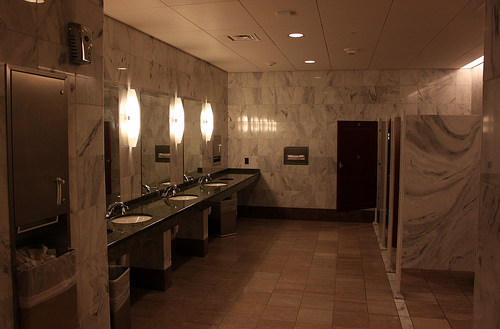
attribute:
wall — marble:
[229, 67, 385, 214]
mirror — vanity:
[102, 88, 121, 204]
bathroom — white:
[7, 2, 495, 324]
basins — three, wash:
[108, 166, 218, 237]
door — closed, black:
[335, 118, 377, 211]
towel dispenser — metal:
[4, 58, 76, 240]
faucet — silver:
[192, 171, 213, 188]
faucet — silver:
[160, 183, 182, 192]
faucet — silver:
[104, 197, 129, 220]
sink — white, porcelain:
[205, 181, 227, 186]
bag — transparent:
[14, 221, 92, 279]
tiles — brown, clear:
[200, 254, 383, 326]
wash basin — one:
[110, 209, 151, 226]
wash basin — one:
[167, 191, 198, 202]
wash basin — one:
[204, 180, 228, 189]